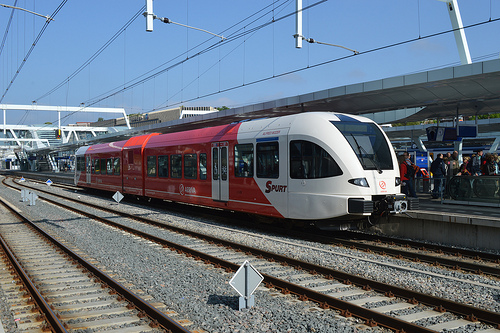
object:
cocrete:
[136, 107, 182, 129]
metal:
[0, 103, 133, 160]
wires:
[0, 0, 500, 143]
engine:
[236, 111, 407, 233]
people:
[395, 144, 499, 200]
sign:
[228, 260, 265, 312]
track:
[1, 172, 500, 332]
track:
[324, 223, 500, 278]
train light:
[395, 177, 401, 184]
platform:
[395, 181, 499, 252]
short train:
[73, 111, 409, 232]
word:
[263, 180, 287, 193]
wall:
[408, 217, 489, 257]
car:
[71, 131, 164, 197]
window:
[285, 138, 344, 179]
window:
[330, 119, 393, 170]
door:
[209, 141, 229, 200]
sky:
[0, 1, 499, 125]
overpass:
[1, 101, 135, 165]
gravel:
[0, 173, 499, 332]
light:
[347, 176, 371, 187]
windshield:
[329, 113, 395, 170]